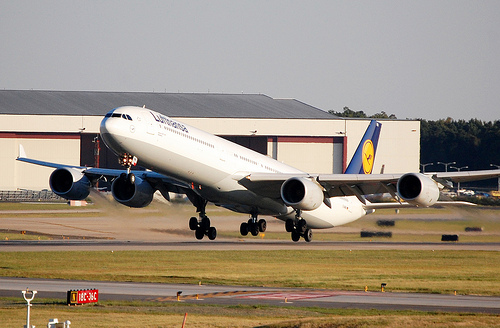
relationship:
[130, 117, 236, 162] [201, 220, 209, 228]
airplane has wheel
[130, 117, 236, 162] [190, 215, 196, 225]
airplane has wheel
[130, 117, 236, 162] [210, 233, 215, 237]
airplane has wheel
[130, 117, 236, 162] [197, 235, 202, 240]
airplane has wheel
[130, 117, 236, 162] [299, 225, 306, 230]
airplane has wheel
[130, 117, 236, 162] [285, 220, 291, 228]
airplane has wheel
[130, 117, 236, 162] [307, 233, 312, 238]
airplane has wheel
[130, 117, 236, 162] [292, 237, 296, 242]
airplane has wheel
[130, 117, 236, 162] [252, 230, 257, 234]
airplane has wheel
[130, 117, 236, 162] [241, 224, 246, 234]
airplane has wheel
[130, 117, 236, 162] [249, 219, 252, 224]
airplane has wheel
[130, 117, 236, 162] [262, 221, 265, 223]
airplane has wheel